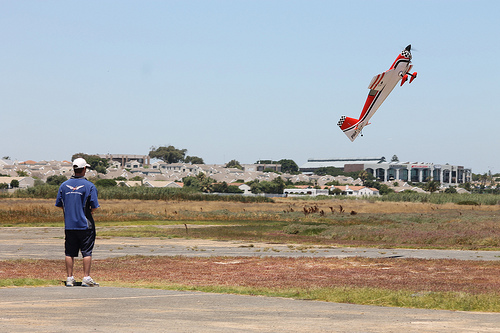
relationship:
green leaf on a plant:
[209, 187, 229, 194] [179, 167, 231, 193]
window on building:
[384, 165, 419, 194] [314, 127, 483, 238]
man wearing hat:
[54, 157, 100, 288] [70, 157, 88, 170]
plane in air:
[350, 47, 409, 135] [164, 16, 236, 83]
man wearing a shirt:
[54, 157, 100, 288] [56, 178, 98, 229]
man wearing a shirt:
[41, 141, 120, 291] [53, 177, 100, 230]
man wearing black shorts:
[54, 157, 100, 288] [63, 224, 99, 258]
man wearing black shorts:
[54, 157, 100, 288] [60, 222, 99, 262]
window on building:
[409, 167, 420, 182] [317, 154, 481, 194]